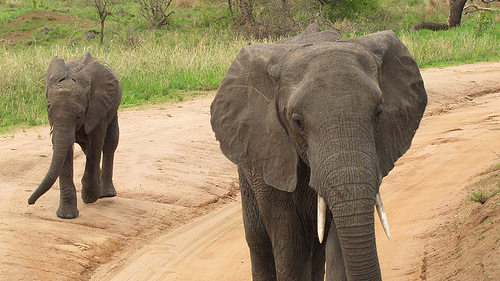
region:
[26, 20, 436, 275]
Picture of two elephants.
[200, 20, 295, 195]
Right ear of elephant on right.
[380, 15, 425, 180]
Left ear of elephant on right.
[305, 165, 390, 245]
Tusks of elephant on right.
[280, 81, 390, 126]
Eyes of elephant on right.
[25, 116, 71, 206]
Trunk of elephant on left.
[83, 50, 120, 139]
Left ear of elephant on left.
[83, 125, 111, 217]
Left front leg of elephant on right.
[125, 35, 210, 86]
Green and brown grass in background.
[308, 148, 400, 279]
Trunk of elephant on right.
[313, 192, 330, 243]
the tusk of an elephant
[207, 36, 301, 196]
the ear of an elephant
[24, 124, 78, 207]
the trunk of an elephant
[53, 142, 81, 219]
the leg of an elephant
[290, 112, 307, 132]
the eye of an elephant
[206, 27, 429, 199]
the head of an elephant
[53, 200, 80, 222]
the foot of an elephant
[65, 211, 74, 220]
the toe of an elephant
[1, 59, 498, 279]
a brown dirt pathway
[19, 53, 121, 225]
a small gray elephant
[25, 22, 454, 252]
two elephants on dirt road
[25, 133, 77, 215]
trunk on young elephant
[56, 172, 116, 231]
walking feet of elephant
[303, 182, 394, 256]
two white tusks on elephant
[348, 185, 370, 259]
lines on trunk skin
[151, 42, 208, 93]
dried brush along road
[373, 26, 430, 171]
ear on elephant's head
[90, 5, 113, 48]
small tree in brush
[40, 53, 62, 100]
elephant ear against head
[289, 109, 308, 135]
eye on elephant's head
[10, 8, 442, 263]
Some elephants walking together.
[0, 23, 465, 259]
Strong elephants walking together.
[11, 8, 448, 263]
Some elephants walking together in daylight.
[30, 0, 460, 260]
Strong elephants out in the daytime.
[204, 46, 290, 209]
huge right ear of an elephant.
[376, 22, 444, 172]
huge left ear of an elephant.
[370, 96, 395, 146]
left eye of an elephant.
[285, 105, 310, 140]
right eye of an elephant.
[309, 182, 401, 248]
an impressive set of elephant tusks.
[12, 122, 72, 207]
the trunk of an elephant.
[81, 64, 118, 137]
Right ear of the elephant in the back.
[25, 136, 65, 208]
The trunk of the elephant in the back.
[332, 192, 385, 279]
The trunk of the elephant in the front.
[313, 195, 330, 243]
The left tusk on the elephant in the front.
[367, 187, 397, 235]
The right tusk of the elephant in the front.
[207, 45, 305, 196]
The left ear of the elephant in the front.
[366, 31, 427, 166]
The right ear of the elephant in the front.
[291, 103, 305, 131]
The left eye of the elephant in the front.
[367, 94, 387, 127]
The right eye of the elephant in the front.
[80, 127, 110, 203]
The right front leg of the elephant in the back.